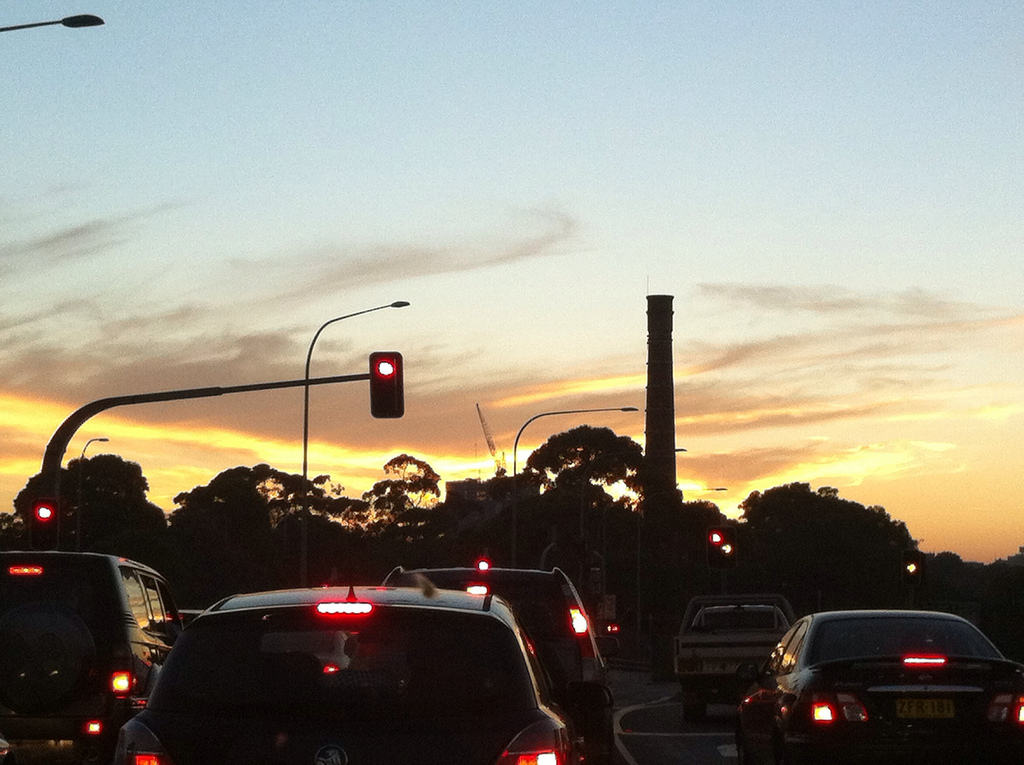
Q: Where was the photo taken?
A: On the street, in the middle of traffic.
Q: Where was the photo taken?
A: At a stop light in city traffic.